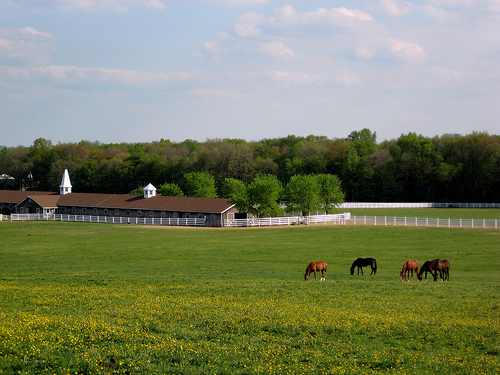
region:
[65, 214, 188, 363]
the grass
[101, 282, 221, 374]
the grass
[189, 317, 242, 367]
the grass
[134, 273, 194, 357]
the grass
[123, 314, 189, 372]
the grass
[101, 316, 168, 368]
the grass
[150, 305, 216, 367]
the grass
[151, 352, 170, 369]
the grass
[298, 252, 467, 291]
the five horses are grazing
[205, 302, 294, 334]
the grass has yellow flowers in it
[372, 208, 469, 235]
the fence is white in color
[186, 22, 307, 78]
the sky has puffy clouds in it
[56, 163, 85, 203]
the steeple on the house is white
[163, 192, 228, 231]
the stable is brown and white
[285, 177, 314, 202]
the tree has bright green leaves on it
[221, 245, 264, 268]
the grass is green in color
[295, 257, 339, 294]
the horse has white on the lower part of it's legs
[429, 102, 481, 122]
the clouds are grayish blue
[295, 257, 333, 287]
a light brown horse on the grass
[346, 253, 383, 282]
a black horse on the grass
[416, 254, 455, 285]
a dark brown horse on the grass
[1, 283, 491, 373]
yellow flowers in the field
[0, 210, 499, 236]
a white wooden fence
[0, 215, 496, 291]
a grassy green field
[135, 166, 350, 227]
a row of green trees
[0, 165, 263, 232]
a brown and white stable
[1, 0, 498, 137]
a cloudy blue sky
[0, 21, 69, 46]
a cloud in the sky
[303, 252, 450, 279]
the horses on teh grass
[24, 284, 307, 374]
the yellow flowers in the field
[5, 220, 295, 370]
large area of grass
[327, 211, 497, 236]
the white fence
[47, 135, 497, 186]
the large area of trees in the back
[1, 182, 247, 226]
the large brown building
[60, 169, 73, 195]
the white steeple on the top of the building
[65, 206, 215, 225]
the windows on the building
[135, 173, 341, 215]
the trees right behind the building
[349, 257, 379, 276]
the black horse on the grass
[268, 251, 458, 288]
Horses grazing on grass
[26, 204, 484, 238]
White fence surrounding the field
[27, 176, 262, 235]
Barn with a brown roof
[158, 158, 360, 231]
Trees by the barn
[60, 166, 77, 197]
Tall white narrow tower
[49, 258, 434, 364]
Yellow flowers in the field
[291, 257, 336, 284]
The horse is chestnut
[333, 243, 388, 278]
The horse is black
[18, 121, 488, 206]
Dense foliage behind the fence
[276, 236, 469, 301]
The horses are standing